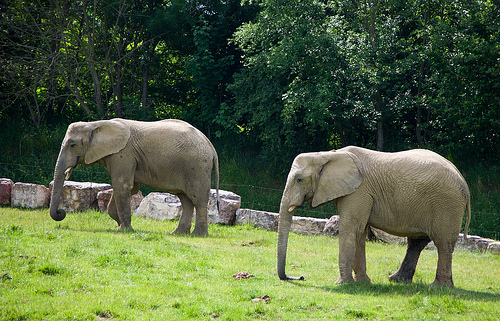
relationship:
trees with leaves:
[12, 12, 482, 124] [228, 24, 289, 74]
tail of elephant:
[212, 151, 224, 219] [46, 113, 225, 246]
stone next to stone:
[94, 185, 139, 220] [143, 185, 180, 220]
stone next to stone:
[143, 185, 180, 220] [178, 185, 235, 221]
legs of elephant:
[429, 209, 463, 291] [277, 145, 469, 291]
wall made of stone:
[2, 164, 490, 257] [11, 176, 49, 216]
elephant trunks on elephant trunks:
[49, 149, 71, 226] [277, 189, 300, 285]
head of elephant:
[262, 152, 364, 226] [266, 133, 473, 303]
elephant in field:
[46, 113, 225, 246] [0, 202, 498, 319]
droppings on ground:
[229, 270, 261, 286] [0, 201, 498, 319]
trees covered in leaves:
[4, 0, 496, 174] [330, 28, 460, 107]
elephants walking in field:
[41, 107, 474, 297] [2, 152, 495, 317]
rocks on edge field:
[9, 180, 50, 207] [0, 202, 498, 319]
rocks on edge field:
[180, 188, 241, 224] [0, 202, 498, 319]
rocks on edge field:
[46, 177, 111, 212] [0, 202, 498, 319]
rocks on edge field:
[206, 187, 240, 224] [0, 202, 498, 319]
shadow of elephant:
[304, 280, 494, 301] [230, 107, 449, 287]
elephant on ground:
[230, 107, 449, 287] [0, 144, 498, 318]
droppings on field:
[229, 270, 261, 280] [0, 202, 498, 319]